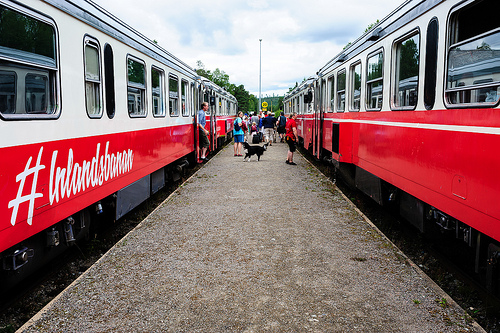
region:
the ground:
[203, 192, 327, 289]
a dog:
[239, 141, 266, 163]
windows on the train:
[6, 15, 58, 111]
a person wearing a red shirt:
[286, 113, 298, 135]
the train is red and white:
[407, 110, 469, 160]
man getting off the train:
[198, 103, 211, 156]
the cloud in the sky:
[268, 13, 310, 74]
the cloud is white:
[270, 38, 304, 73]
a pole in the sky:
[253, 40, 269, 89]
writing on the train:
[48, 135, 140, 195]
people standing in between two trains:
[196, 91, 314, 159]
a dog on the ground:
[241, 135, 267, 155]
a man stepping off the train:
[194, 99, 218, 149]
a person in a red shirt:
[283, 111, 304, 149]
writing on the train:
[11, 148, 163, 204]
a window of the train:
[2, 9, 72, 96]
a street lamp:
[253, 32, 263, 101]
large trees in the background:
[205, 60, 266, 110]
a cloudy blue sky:
[177, 3, 347, 71]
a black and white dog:
[241, 138, 270, 156]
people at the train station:
[175, 82, 315, 187]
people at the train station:
[194, 84, 305, 191]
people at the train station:
[168, 83, 338, 183]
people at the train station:
[170, 63, 337, 198]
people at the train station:
[157, 65, 329, 178]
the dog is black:
[232, 130, 282, 161]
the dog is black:
[232, 130, 270, 164]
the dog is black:
[234, 132, 286, 172]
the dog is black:
[222, 116, 288, 170]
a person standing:
[232, 109, 244, 158]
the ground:
[201, 194, 333, 304]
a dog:
[237, 140, 272, 160]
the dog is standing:
[238, 138, 265, 161]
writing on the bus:
[34, 153, 148, 183]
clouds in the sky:
[268, 28, 319, 70]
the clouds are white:
[211, 20, 249, 62]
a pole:
[258, 44, 265, 94]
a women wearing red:
[284, 118, 294, 133]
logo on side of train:
[1, 130, 143, 234]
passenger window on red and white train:
[0, 2, 62, 119]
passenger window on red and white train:
[81, 34, 103, 118]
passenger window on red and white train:
[103, 41, 115, 116]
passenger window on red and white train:
[126, 54, 148, 119]